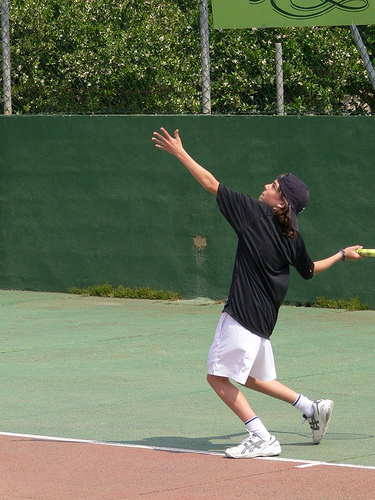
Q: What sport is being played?
A: Tennis.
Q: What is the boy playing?
A: Tennis.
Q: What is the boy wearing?
A: A black polo shirt.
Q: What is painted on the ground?
A: White lines.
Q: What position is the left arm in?
A: Raised?.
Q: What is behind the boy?
A: A green wall.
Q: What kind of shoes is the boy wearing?
A: Athletic shoes.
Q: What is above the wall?
A: A fence.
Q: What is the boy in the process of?
A: Serving.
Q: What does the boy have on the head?
A: A hat.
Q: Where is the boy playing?
A: Tennis court.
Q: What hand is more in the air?
A: Left hand.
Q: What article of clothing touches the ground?
A: Shoes.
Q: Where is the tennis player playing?
A: At a tennis court.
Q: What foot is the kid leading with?
A: Left foot.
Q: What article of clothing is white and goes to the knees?
A: Shorts.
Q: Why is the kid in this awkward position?
A: Serving a ball.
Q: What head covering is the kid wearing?
A: A hat.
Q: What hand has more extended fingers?
A: Left hand.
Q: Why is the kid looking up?
A: To watch the ball.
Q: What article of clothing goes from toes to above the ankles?
A: Socks.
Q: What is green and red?
A: Tennis court.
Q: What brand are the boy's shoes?
A: Asic.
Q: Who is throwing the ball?
A: The boy.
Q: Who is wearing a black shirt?
A: The boy.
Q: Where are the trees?
A: Outside the court.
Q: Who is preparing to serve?
A: The boy.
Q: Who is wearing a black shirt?
A: The boy.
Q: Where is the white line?
A: On court.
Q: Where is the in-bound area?
A: On court.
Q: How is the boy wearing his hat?
A: Backwards.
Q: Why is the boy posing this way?
A: He is about to serve a tennis ball.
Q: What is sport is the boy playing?
A: Tennis.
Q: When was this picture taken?
A: Daytime.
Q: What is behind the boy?
A: A green wall.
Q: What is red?
A: Section of the court in front of the boy.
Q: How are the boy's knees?
A: Bent.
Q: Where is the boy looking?
A: Up.